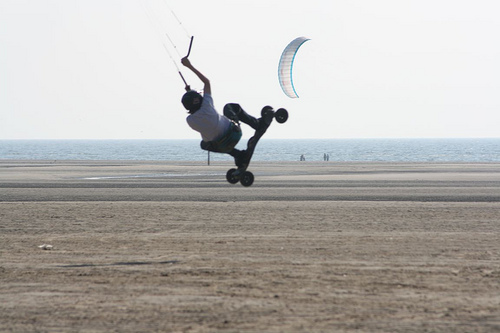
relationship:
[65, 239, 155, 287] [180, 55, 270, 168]
shadow of man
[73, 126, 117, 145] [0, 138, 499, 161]
surface of ocean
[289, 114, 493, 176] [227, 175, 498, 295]
ocean by beach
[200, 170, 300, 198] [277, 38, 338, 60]
wheels on object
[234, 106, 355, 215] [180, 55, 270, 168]
object under man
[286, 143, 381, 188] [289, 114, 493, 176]
people in background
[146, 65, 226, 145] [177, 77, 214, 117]
man has head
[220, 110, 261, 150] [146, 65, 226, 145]
leg of man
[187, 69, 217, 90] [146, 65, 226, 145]
arm of man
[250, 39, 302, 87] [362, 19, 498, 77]
kite in sky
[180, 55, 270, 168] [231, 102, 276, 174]
man on skateboard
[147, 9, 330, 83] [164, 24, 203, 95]
parasail has handles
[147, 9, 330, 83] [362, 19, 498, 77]
parasail in sky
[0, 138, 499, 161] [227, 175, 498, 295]
ocean by beach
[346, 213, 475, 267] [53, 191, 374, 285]
sand on ground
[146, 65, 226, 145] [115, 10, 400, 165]
man in air